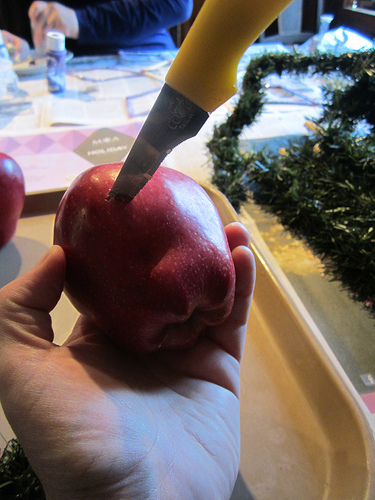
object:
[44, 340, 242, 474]
palm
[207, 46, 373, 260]
needles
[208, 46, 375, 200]
garland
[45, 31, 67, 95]
tube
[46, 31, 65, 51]
cap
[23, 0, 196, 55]
person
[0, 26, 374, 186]
table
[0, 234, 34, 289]
shadow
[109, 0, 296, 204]
knife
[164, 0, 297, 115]
handle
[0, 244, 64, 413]
thumb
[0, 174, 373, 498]
tray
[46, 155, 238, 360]
suitcase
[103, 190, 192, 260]
skin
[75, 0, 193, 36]
sleeve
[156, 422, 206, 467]
reflection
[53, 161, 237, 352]
apple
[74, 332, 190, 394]
shadow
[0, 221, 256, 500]
hand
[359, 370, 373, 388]
facebook logo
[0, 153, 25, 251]
apple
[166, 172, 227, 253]
reflection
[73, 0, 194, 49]
shirt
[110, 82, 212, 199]
blade